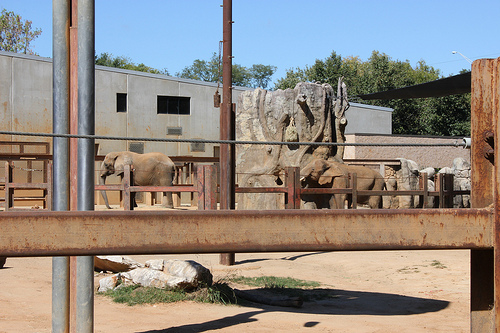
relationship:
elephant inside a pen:
[297, 157, 384, 212] [0, 133, 474, 330]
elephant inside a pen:
[300, 158, 389, 209] [0, 133, 474, 330]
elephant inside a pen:
[98, 151, 177, 209] [0, 133, 474, 330]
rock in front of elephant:
[236, 79, 344, 208] [300, 158, 389, 209]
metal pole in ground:
[45, 9, 112, 331] [0, 202, 473, 331]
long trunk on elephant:
[98, 168, 113, 209] [97, 150, 180, 205]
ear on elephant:
[314, 160, 341, 185] [300, 158, 389, 209]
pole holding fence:
[2, 203, 497, 249] [0, 58, 496, 329]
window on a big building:
[155, 94, 191, 114] [0, 50, 393, 207]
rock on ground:
[98, 258, 213, 295] [0, 202, 473, 331]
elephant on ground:
[300, 158, 389, 209] [0, 202, 473, 331]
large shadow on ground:
[219, 274, 464, 328] [0, 202, 473, 331]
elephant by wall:
[99, 150, 178, 209] [4, 59, 225, 201]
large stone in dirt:
[119, 244, 217, 308] [0, 204, 472, 331]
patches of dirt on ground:
[346, 256, 395, 320] [281, 262, 461, 324]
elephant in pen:
[300, 158, 389, 209] [9, 139, 466, 214]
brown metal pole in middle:
[211, 1, 259, 267] [153, 8, 313, 310]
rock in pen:
[98, 258, 213, 295] [9, 169, 483, 308]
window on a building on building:
[116, 92, 127, 112] [9, 34, 397, 164]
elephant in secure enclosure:
[300, 158, 389, 209] [5, 126, 498, 274]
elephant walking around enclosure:
[98, 151, 177, 209] [12, 139, 484, 263]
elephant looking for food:
[300, 158, 389, 209] [242, 143, 300, 201]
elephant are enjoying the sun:
[300, 158, 389, 209] [35, 107, 464, 260]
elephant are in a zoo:
[98, 151, 177, 209] [14, 57, 484, 198]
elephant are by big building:
[98, 151, 177, 209] [4, 50, 406, 199]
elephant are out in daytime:
[300, 158, 389, 209] [5, 27, 480, 308]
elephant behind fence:
[300, 158, 389, 209] [14, 178, 471, 273]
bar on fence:
[14, 203, 480, 253] [13, 126, 484, 273]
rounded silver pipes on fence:
[4, 129, 491, 149] [18, 43, 484, 283]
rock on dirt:
[108, 258, 211, 294] [240, 257, 460, 330]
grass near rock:
[94, 280, 240, 307] [103, 259, 205, 297]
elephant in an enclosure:
[300, 158, 389, 209] [13, 40, 488, 325]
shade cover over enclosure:
[338, 62, 491, 146] [16, 95, 466, 277]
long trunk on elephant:
[290, 160, 318, 201] [290, 147, 399, 210]